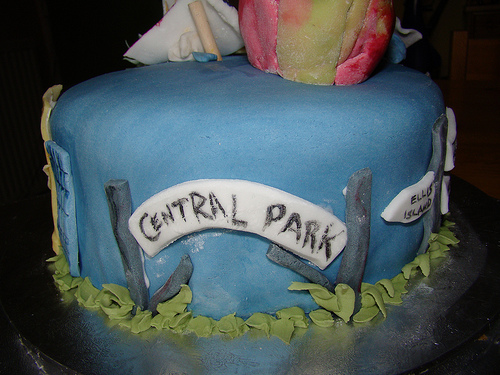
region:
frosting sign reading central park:
[125, 181, 344, 274]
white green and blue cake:
[35, 1, 477, 338]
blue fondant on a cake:
[100, 178, 147, 315]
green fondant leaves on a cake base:
[157, 313, 323, 338]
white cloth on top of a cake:
[119, 1, 241, 64]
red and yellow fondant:
[238, 0, 398, 86]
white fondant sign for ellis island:
[382, 177, 433, 224]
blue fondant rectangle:
[42, 138, 78, 284]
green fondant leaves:
[60, 276, 100, 308]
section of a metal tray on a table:
[0, 336, 497, 373]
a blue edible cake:
[38, 50, 460, 345]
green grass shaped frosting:
[291, 274, 355, 324]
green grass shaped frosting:
[244, 304, 309, 344]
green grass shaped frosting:
[151, 287, 188, 334]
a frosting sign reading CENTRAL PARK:
[127, 179, 347, 273]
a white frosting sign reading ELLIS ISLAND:
[382, 168, 437, 227]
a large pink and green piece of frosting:
[237, 0, 408, 86]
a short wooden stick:
[178, 2, 223, 62]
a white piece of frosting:
[168, 30, 195, 66]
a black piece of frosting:
[102, 179, 151, 316]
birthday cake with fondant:
[31, 7, 470, 351]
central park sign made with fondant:
[88, 162, 403, 333]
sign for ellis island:
[385, 150, 445, 241]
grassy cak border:
[53, 247, 468, 340]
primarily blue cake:
[46, 89, 443, 313]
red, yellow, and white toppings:
[131, 4, 431, 118]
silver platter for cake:
[15, 176, 495, 373]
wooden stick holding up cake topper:
[164, 9, 240, 66]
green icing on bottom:
[59, 253, 466, 340]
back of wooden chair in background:
[427, 25, 496, 193]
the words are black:
[135, 200, 329, 255]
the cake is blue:
[14, 4, 489, 344]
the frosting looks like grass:
[220, 301, 298, 338]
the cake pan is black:
[60, 325, 113, 370]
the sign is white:
[128, 196, 349, 270]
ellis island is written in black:
[400, 183, 436, 218]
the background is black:
[15, 11, 86, 57]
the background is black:
[42, 23, 104, 49]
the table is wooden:
[470, 121, 490, 176]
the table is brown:
[474, 141, 496, 175]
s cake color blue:
[25, 4, 476, 351]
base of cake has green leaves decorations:
[23, 0, 483, 342]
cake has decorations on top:
[151, 0, 475, 185]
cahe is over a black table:
[22, 3, 490, 357]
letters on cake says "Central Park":
[94, 116, 407, 363]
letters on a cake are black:
[111, 168, 361, 290]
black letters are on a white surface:
[107, 168, 355, 284]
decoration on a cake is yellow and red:
[233, 1, 439, 138]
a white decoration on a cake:
[116, 5, 248, 93]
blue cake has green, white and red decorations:
[20, 3, 498, 359]